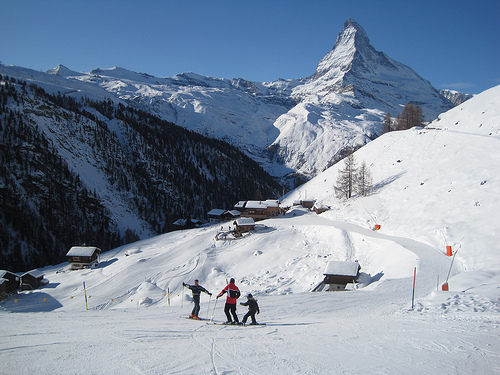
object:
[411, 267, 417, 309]
pole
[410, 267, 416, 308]
flag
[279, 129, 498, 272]
slope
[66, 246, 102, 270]
building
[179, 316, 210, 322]
skis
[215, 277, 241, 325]
person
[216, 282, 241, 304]
coat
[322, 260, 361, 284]
cabin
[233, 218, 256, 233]
cabin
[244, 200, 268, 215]
cabin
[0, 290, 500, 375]
slope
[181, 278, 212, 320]
people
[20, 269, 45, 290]
building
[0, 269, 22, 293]
building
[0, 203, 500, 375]
ground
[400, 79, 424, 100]
ground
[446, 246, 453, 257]
flag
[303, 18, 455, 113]
mountain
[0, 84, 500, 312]
mountainside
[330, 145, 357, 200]
trees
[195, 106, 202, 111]
snow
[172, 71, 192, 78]
mountain ridge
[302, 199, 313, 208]
houses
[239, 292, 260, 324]
child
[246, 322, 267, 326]
skis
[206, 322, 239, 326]
skis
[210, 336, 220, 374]
track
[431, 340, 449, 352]
track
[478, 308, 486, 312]
track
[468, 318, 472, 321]
track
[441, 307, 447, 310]
track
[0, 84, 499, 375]
snow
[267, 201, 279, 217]
house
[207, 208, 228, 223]
house